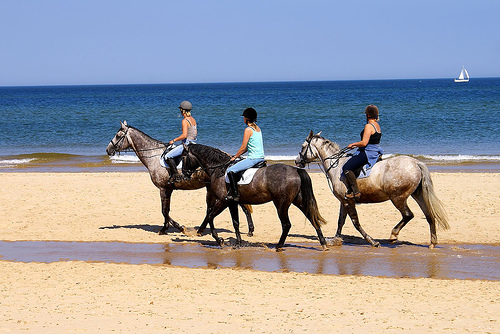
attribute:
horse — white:
[293, 130, 452, 252]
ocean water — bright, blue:
[76, 103, 388, 150]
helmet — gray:
[177, 98, 194, 113]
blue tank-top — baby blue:
[238, 120, 266, 160]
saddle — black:
[231, 154, 264, 185]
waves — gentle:
[430, 148, 492, 167]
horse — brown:
[179, 140, 329, 254]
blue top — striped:
[238, 122, 268, 161]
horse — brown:
[98, 66, 463, 291]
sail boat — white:
[453, 66, 478, 89]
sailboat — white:
[453, 65, 471, 82]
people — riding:
[99, 105, 448, 249]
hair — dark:
[243, 108, 256, 126]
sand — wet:
[6, 230, 484, 290]